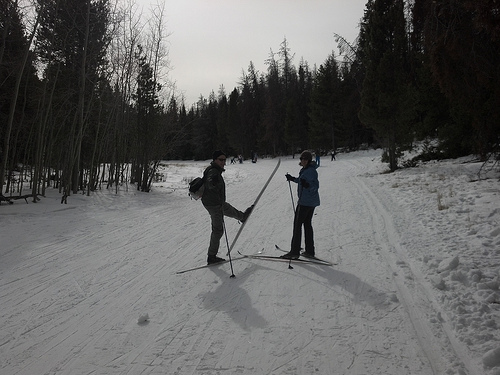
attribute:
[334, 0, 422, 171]
tree — tall, green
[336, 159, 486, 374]
trail — long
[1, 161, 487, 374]
path — smooth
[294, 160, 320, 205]
jacket — blue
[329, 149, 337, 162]
person — skiing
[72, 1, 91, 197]
tree — bare, brown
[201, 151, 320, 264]
couple — posing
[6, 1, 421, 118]
sky — gray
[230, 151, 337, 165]
people — further